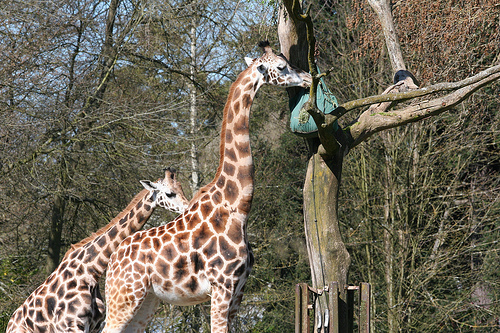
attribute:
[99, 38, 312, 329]
tall giraffe — looking at the tree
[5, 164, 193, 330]
smaller giraffe — standing behind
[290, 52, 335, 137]
blue bag — in the tree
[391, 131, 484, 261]
bare branches — on the tree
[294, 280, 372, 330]
fence — wooden, makeshift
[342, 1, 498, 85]
leaves — few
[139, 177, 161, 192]
ear — white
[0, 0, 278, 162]
sky — blue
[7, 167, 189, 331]
giraffe — baby, small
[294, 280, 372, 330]
posts — wooden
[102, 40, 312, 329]
giraffe — tall, large, adult, orange, brown, eating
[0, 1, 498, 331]
trees — brown, green, bare, lots, tall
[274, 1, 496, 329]
moss — green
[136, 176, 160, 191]
ear — tan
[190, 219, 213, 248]
spot — dark brown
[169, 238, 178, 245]
spot — white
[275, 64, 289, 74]
eye — slanted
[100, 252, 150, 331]
leg — wide, hind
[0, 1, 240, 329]
tree — bare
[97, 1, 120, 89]
branch — large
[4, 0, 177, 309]
tree — leafless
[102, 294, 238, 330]
legs — back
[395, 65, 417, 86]
object — black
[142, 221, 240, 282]
spots — black, brown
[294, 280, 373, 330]
object — wooden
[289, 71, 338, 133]
sack — green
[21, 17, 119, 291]
tree — bare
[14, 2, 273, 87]
sky — cloudless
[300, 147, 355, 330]
tree — dark grey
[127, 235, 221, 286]
skin — colorful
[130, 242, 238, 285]
spots — brown, white